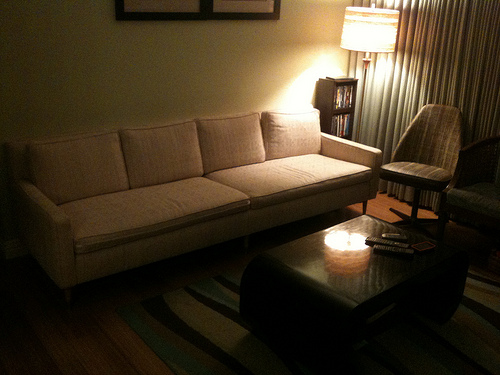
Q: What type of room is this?
A: It is a living room.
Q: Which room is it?
A: It is a living room.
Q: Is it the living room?
A: Yes, it is the living room.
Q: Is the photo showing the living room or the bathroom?
A: It is showing the living room.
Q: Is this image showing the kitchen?
A: No, the picture is showing the living room.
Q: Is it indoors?
A: Yes, it is indoors.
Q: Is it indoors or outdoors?
A: It is indoors.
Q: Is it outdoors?
A: No, it is indoors.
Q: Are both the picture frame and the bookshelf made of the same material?
A: Yes, both the picture frame and the bookshelf are made of wood.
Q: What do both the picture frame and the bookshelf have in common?
A: The material, both the picture frame and the bookshelf are wooden.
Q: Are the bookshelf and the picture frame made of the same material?
A: Yes, both the bookshelf and the picture frame are made of wood.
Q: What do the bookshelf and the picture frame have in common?
A: The material, both the bookshelf and the picture frame are wooden.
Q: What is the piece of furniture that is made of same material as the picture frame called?
A: The piece of furniture is a bookshelf.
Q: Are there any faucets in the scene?
A: No, there are no faucets.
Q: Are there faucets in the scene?
A: No, there are no faucets.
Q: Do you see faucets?
A: No, there are no faucets.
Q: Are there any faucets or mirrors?
A: No, there are no faucets or mirrors.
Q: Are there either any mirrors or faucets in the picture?
A: No, there are no faucets or mirrors.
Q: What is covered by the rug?
A: The floor is covered by the rug.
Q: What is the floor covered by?
A: The floor is covered by the rug.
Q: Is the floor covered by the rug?
A: Yes, the floor is covered by the rug.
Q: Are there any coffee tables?
A: Yes, there is a coffee table.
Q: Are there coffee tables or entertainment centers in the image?
A: Yes, there is a coffee table.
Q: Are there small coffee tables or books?
A: Yes, there is a small coffee table.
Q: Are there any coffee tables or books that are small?
A: Yes, the coffee table is small.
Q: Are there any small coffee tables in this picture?
A: Yes, there is a small coffee table.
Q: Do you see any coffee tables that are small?
A: Yes, there is a coffee table that is small.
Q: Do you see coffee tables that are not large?
A: Yes, there is a small coffee table.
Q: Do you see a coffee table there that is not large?
A: Yes, there is a small coffee table.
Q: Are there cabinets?
A: No, there are no cabinets.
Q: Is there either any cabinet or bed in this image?
A: No, there are no cabinets or beds.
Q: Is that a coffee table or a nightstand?
A: That is a coffee table.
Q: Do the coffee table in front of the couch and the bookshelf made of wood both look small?
A: Yes, both the coffee table and the bookshelf are small.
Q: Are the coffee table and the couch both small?
A: Yes, both the coffee table and the couch are small.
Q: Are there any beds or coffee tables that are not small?
A: No, there is a coffee table but it is small.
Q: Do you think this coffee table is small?
A: Yes, the coffee table is small.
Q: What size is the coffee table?
A: The coffee table is small.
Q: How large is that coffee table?
A: The coffee table is small.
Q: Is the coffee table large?
A: No, the coffee table is small.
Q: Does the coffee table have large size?
A: No, the coffee table is small.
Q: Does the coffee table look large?
A: No, the coffee table is small.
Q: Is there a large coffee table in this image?
A: No, there is a coffee table but it is small.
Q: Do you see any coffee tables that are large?
A: No, there is a coffee table but it is small.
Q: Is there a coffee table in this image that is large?
A: No, there is a coffee table but it is small.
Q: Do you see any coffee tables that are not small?
A: No, there is a coffee table but it is small.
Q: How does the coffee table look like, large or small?
A: The coffee table is small.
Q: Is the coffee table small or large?
A: The coffee table is small.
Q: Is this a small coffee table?
A: Yes, this is a small coffee table.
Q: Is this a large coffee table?
A: No, this is a small coffee table.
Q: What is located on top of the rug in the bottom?
A: The coffee table is on top of the rug.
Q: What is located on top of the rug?
A: The coffee table is on top of the rug.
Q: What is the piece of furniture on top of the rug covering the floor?
A: The piece of furniture is a coffee table.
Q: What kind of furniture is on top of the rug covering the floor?
A: The piece of furniture is a coffee table.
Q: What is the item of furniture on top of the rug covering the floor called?
A: The piece of furniture is a coffee table.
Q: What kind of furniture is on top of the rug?
A: The piece of furniture is a coffee table.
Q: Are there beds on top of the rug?
A: No, there is a coffee table on top of the rug.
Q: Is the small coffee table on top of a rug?
A: Yes, the coffee table is on top of a rug.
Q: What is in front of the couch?
A: The coffee table is in front of the couch.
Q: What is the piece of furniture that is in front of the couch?
A: The piece of furniture is a coffee table.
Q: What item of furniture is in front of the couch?
A: The piece of furniture is a coffee table.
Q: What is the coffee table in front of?
A: The coffee table is in front of the couch.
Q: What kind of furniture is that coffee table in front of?
A: The coffee table is in front of the couch.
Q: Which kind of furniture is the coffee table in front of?
A: The coffee table is in front of the couch.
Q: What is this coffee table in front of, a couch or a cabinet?
A: The coffee table is in front of a couch.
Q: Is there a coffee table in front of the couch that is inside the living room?
A: Yes, there is a coffee table in front of the couch.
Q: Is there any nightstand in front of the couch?
A: No, there is a coffee table in front of the couch.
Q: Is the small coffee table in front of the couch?
A: Yes, the coffee table is in front of the couch.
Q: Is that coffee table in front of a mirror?
A: No, the coffee table is in front of the couch.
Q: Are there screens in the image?
A: No, there are no screens.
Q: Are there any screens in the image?
A: No, there are no screens.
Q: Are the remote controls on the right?
A: Yes, the remote controls are on the right of the image.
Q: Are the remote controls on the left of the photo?
A: No, the remote controls are on the right of the image.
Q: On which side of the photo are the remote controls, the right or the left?
A: The remote controls are on the right of the image.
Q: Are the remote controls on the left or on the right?
A: The remote controls are on the right of the image.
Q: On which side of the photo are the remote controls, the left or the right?
A: The remote controls are on the right of the image.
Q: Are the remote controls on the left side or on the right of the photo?
A: The remote controls are on the right of the image.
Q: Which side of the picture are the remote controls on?
A: The remote controls are on the right of the image.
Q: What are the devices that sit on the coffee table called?
A: The devices are remote controls.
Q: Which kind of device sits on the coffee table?
A: The devices are remote controls.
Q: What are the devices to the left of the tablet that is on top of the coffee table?
A: The devices are remote controls.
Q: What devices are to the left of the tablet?
A: The devices are remote controls.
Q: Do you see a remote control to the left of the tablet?
A: Yes, there are remote controls to the left of the tablet.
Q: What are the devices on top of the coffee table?
A: The devices are remote controls.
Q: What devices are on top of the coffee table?
A: The devices are remote controls.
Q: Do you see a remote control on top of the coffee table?
A: Yes, there are remote controls on top of the coffee table.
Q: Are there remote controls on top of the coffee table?
A: Yes, there are remote controls on top of the coffee table.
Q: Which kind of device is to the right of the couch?
A: The devices are remote controls.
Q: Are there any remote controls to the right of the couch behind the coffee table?
A: Yes, there are remote controls to the right of the couch.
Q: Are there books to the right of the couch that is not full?
A: No, there are remote controls to the right of the couch.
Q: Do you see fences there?
A: No, there are no fences.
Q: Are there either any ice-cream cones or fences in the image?
A: No, there are no fences or ice-cream cones.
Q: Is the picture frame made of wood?
A: Yes, the picture frame is made of wood.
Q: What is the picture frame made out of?
A: The picture frame is made of wood.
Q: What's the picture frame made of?
A: The picture frame is made of wood.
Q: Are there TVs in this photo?
A: No, there are no tvs.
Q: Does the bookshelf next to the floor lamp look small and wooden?
A: Yes, the bookshelf is small and wooden.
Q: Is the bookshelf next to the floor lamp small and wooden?
A: Yes, the bookshelf is small and wooden.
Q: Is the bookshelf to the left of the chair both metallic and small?
A: No, the bookshelf is small but wooden.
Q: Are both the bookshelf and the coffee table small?
A: Yes, both the bookshelf and the coffee table are small.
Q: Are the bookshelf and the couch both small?
A: Yes, both the bookshelf and the couch are small.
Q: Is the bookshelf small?
A: Yes, the bookshelf is small.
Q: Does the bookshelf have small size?
A: Yes, the bookshelf is small.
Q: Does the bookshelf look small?
A: Yes, the bookshelf is small.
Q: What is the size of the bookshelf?
A: The bookshelf is small.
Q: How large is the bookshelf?
A: The bookshelf is small.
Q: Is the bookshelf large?
A: No, the bookshelf is small.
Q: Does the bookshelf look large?
A: No, the bookshelf is small.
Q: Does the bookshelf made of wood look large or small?
A: The bookshelf is small.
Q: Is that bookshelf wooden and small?
A: Yes, the bookshelf is wooden and small.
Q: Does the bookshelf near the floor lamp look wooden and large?
A: No, the bookshelf is wooden but small.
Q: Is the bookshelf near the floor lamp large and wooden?
A: No, the bookshelf is wooden but small.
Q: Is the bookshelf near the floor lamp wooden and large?
A: No, the bookshelf is wooden but small.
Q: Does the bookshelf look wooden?
A: Yes, the bookshelf is wooden.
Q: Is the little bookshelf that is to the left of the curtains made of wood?
A: Yes, the bookshelf is made of wood.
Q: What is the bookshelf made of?
A: The bookshelf is made of wood.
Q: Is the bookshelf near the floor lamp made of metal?
A: No, the bookshelf is made of wood.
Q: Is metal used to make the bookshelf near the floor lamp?
A: No, the bookshelf is made of wood.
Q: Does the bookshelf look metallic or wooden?
A: The bookshelf is wooden.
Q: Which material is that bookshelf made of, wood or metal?
A: The bookshelf is made of wood.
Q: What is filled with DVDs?
A: The bookshelf is filled with DVDs.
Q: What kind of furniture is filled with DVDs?
A: The piece of furniture is a bookshelf.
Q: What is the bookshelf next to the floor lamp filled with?
A: The bookshelf is filled with DVDs.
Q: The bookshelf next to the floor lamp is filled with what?
A: The bookshelf is filled with DVDs.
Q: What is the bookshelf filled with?
A: The bookshelf is filled with DVDs.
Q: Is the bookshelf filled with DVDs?
A: Yes, the bookshelf is filled with DVDs.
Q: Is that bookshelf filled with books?
A: No, the bookshelf is filled with DVDs.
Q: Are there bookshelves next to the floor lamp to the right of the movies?
A: Yes, there is a bookshelf next to the floor lamp.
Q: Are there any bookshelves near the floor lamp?
A: Yes, there is a bookshelf near the floor lamp.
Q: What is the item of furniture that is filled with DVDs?
A: The piece of furniture is a bookshelf.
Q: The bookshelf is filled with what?
A: The bookshelf is filled with DVDs.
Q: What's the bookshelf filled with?
A: The bookshelf is filled with DVDs.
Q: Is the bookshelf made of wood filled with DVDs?
A: Yes, the bookshelf is filled with DVDs.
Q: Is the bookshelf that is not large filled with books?
A: No, the bookshelf is filled with DVDs.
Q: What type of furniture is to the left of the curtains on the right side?
A: The piece of furniture is a bookshelf.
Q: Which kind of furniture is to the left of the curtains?
A: The piece of furniture is a bookshelf.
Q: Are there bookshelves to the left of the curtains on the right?
A: Yes, there is a bookshelf to the left of the curtains.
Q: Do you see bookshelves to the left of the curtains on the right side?
A: Yes, there is a bookshelf to the left of the curtains.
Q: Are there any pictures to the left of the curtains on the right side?
A: No, there is a bookshelf to the left of the curtains.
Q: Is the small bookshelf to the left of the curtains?
A: Yes, the bookshelf is to the left of the curtains.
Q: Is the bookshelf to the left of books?
A: No, the bookshelf is to the left of the curtains.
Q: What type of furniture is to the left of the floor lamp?
A: The piece of furniture is a bookshelf.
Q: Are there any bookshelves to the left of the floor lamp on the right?
A: Yes, there is a bookshelf to the left of the floor lamp.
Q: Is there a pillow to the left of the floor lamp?
A: No, there is a bookshelf to the left of the floor lamp.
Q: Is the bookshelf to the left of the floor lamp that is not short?
A: Yes, the bookshelf is to the left of the floor lamp.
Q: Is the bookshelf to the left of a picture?
A: No, the bookshelf is to the left of the floor lamp.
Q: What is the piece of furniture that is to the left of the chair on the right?
A: The piece of furniture is a bookshelf.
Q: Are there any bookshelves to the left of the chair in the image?
A: Yes, there is a bookshelf to the left of the chair.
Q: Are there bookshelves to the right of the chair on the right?
A: No, the bookshelf is to the left of the chair.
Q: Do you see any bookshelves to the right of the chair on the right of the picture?
A: No, the bookshelf is to the left of the chair.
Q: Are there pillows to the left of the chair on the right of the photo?
A: No, there is a bookshelf to the left of the chair.